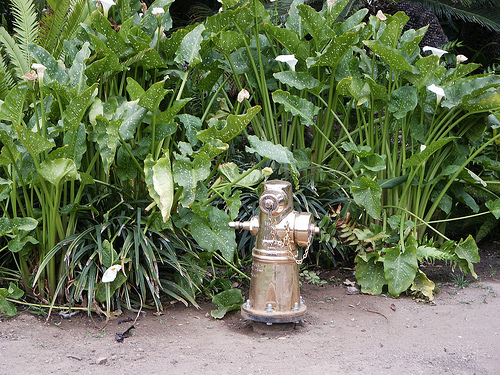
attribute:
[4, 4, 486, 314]
leaves — many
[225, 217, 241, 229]
nut — side